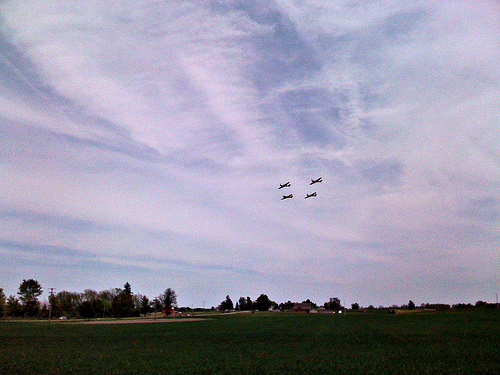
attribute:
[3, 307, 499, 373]
field — large, green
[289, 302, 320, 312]
buildings — distant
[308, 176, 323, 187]
airplane — far away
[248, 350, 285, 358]
grass — green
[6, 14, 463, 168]
sky — cloudy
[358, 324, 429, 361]
grass — green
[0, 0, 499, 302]
clouds — white